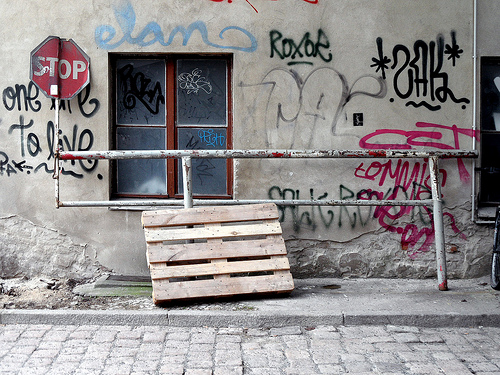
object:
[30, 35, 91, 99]
sign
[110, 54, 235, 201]
window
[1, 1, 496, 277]
wall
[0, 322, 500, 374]
floor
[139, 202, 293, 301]
wood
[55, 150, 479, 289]
fence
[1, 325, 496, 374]
street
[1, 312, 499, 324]
curb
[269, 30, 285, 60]
words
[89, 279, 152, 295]
slab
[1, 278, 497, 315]
sidewalk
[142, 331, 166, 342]
bricks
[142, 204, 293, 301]
pallet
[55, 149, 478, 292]
gate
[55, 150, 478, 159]
bar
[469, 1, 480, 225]
pipe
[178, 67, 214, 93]
graffiti